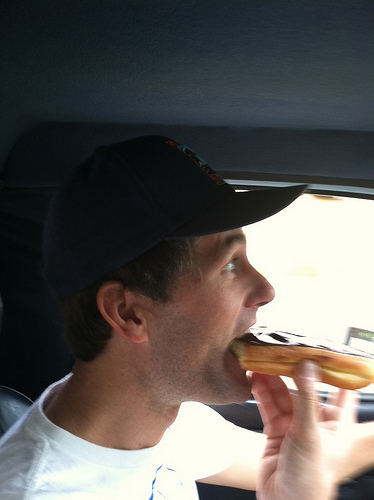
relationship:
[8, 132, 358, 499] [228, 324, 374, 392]
man eating a eclair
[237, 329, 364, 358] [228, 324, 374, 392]
icing on eclair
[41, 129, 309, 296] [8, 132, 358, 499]
hat on man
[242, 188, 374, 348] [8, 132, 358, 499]
light behind man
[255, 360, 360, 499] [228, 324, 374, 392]
hand holding eclair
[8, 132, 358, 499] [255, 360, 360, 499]
man has a hand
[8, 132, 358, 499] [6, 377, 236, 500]
man in a t-shirt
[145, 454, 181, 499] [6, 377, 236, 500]
design on t-shirt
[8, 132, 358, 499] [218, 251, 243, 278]
man has an eye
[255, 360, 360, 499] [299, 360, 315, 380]
hand has fingernail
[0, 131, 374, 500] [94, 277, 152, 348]
man has ear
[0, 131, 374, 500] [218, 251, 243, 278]
man has an eye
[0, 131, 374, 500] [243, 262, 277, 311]
man has a nose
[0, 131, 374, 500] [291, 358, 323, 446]
man has a thumb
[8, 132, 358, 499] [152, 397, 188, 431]
man has adam's apple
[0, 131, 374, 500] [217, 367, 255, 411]
man has a chin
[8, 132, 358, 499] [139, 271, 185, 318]
man has sideburns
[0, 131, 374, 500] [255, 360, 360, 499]
man has a hand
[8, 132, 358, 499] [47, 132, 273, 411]
man has a head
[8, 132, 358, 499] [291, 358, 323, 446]
man has a thumb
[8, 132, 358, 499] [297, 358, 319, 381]
man has a thumbnail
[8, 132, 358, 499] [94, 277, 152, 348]
man has ear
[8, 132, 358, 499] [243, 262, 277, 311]
man has a nose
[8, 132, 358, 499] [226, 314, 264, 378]
man has a mouth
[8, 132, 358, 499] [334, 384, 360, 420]
man has finger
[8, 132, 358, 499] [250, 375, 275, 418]
man has finger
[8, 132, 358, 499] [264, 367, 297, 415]
man has finger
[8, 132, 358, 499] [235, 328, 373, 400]
man eating an eclair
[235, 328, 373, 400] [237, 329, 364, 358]
eclair has icing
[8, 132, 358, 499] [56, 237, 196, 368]
man has hair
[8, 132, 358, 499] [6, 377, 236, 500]
man wearing a t-shirt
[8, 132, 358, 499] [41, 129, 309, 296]
man has hat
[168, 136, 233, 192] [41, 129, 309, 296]
logo on hat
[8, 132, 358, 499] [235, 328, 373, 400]
man holding an eclair